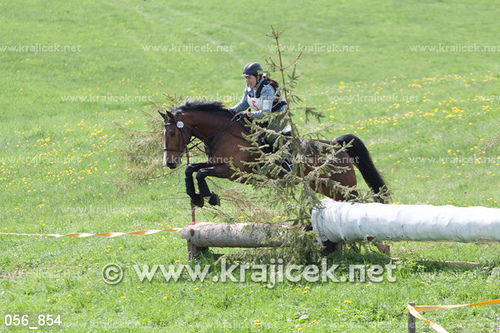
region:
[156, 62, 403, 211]
a rider on a horse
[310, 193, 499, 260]
white wrapping on a pole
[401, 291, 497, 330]
orange rope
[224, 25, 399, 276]
a small fur tree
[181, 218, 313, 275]
a wood poll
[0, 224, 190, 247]
orange rope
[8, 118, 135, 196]
yellow flowers in a field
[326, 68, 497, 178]
yellow flowers in a field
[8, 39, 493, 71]
white flowers in a field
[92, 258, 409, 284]
writing on photo that says "(c) www.krajicek.net"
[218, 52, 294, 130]
A man riding a brown horse.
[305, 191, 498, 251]
a long metal pipe.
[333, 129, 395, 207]
a black horse tail.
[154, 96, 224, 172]
a brown horse head.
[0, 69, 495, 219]
a field of yellow flowers.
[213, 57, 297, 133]
a man riding a brown horse.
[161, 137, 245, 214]
the front end of a horse.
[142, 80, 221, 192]
a large brown horse head.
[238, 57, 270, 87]
a helmet on a head.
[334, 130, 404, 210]
a long horse tail.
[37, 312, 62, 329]
the number 854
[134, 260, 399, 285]
the address www.krajicek.net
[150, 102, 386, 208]
a brown horse jumping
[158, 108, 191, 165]
the head of the horse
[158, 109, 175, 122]
the two ears of the horse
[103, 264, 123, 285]
the copyright symbol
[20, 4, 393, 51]
a lot of grass in the field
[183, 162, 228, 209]
two legs of the horse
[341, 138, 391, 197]
the wide tail of the horse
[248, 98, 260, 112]
the number 5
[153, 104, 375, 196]
brown horse jumping over log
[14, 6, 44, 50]
short green and yellow grass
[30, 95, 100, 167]
short green and yellow grass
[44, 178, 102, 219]
short green and yellow grass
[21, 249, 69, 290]
short green and yellow grass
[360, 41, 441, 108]
short green and yellow grass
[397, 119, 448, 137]
short green and yellow grass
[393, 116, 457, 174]
short green and yellow grass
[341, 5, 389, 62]
short green and yellow grass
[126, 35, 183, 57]
short green and yellow grass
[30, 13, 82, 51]
short green and yellow grass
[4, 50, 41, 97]
short green and yellow grass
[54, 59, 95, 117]
short green and yellow grass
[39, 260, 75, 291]
short green and yellow grass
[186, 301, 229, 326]
short green and yellow grass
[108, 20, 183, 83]
short green and yellow grass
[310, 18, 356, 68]
short green and yellow grass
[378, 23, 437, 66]
short green and yellow grass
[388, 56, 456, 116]
short green and yellow grass